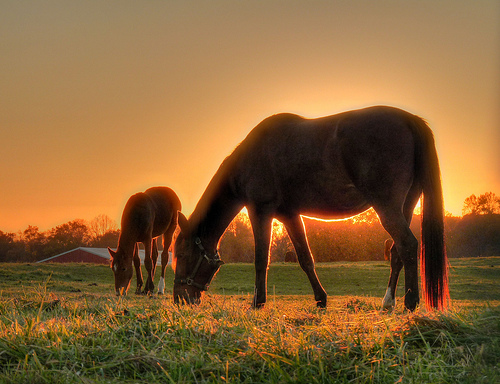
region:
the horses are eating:
[103, 98, 458, 320]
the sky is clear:
[70, 25, 218, 102]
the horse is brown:
[155, 79, 481, 329]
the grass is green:
[72, 301, 214, 371]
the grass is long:
[51, 298, 176, 375]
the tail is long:
[405, 136, 457, 316]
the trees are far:
[25, 215, 109, 270]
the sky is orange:
[40, 79, 141, 279]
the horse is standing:
[132, 100, 497, 310]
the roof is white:
[47, 230, 147, 290]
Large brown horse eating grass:
[148, 85, 474, 338]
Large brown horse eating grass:
[95, 175, 190, 311]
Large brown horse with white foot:
[87, 173, 203, 322]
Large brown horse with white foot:
[152, 87, 461, 341]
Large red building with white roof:
[24, 227, 130, 274]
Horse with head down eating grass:
[87, 168, 195, 321]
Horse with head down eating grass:
[162, 88, 477, 324]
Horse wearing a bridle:
[144, 86, 482, 338]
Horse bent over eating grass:
[95, 178, 191, 305]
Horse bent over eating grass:
[165, 87, 467, 344]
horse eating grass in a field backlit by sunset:
[164, 99, 462, 314]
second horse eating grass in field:
[109, 159, 193, 301]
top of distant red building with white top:
[39, 237, 104, 288]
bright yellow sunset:
[437, 142, 484, 232]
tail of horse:
[417, 128, 462, 308]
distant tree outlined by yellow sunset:
[460, 175, 497, 253]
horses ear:
[172, 208, 192, 235]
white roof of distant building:
[35, 236, 156, 264]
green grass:
[58, 295, 225, 377]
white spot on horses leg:
[152, 271, 178, 298]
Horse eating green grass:
[168, 94, 463, 326]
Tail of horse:
[412, 124, 459, 326]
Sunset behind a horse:
[200, 93, 493, 238]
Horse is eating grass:
[100, 170, 185, 313]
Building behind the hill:
[33, 241, 172, 271]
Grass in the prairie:
[3, 259, 497, 376]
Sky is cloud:
[3, 8, 497, 100]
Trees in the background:
[1, 194, 499, 262]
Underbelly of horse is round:
[300, 191, 375, 226]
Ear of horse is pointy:
[170, 202, 191, 239]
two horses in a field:
[88, 107, 453, 311]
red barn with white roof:
[31, 241, 176, 263]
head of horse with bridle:
[171, 211, 224, 306]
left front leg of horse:
[242, 205, 274, 312]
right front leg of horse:
[276, 208, 331, 308]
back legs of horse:
[361, 171, 425, 316]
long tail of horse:
[408, 109, 451, 315]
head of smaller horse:
[105, 241, 136, 299]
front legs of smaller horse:
[130, 237, 156, 297]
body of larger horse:
[263, 105, 377, 222]